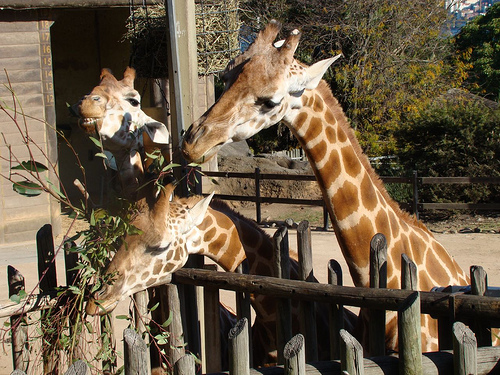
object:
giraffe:
[176, 24, 500, 345]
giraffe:
[69, 65, 174, 205]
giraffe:
[77, 184, 364, 346]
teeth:
[77, 116, 103, 125]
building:
[2, 2, 221, 244]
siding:
[2, 24, 37, 47]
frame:
[159, 7, 196, 195]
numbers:
[39, 11, 56, 108]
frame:
[39, 12, 68, 239]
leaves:
[87, 209, 104, 226]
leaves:
[350, 90, 395, 113]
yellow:
[427, 66, 437, 76]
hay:
[118, 7, 244, 77]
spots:
[300, 97, 384, 236]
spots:
[194, 218, 243, 262]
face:
[207, 67, 293, 146]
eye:
[257, 95, 282, 113]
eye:
[126, 95, 139, 112]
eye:
[145, 241, 172, 260]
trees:
[313, 3, 500, 158]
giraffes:
[88, 168, 379, 375]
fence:
[195, 170, 495, 226]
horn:
[281, 28, 306, 56]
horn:
[121, 64, 138, 90]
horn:
[155, 185, 179, 212]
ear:
[303, 51, 345, 90]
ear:
[140, 113, 172, 147]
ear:
[189, 190, 218, 229]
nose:
[185, 123, 206, 145]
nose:
[80, 95, 103, 107]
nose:
[89, 280, 115, 298]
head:
[181, 29, 327, 166]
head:
[75, 67, 143, 149]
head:
[85, 188, 196, 315]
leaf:
[10, 180, 43, 198]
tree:
[6, 99, 168, 374]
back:
[334, 100, 447, 256]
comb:
[331, 96, 358, 150]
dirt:
[259, 179, 306, 197]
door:
[50, 6, 184, 235]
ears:
[184, 189, 216, 225]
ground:
[459, 233, 500, 264]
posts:
[252, 167, 264, 226]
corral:
[170, 215, 500, 374]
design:
[311, 140, 384, 248]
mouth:
[75, 107, 102, 134]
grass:
[160, 160, 184, 175]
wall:
[2, 11, 61, 244]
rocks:
[430, 227, 448, 237]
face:
[77, 83, 142, 147]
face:
[111, 221, 191, 294]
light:
[233, 70, 261, 91]